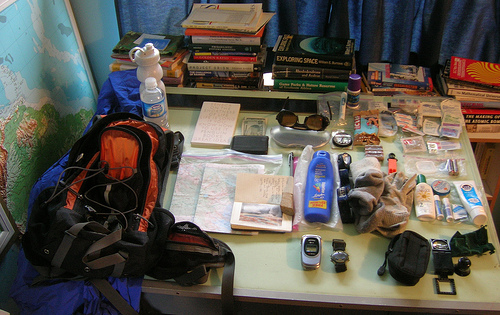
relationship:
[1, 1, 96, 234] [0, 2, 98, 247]
map on wall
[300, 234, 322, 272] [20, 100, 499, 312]
cell phone on desk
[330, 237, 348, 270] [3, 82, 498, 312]
watch on desk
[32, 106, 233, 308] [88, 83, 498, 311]
backpack on desk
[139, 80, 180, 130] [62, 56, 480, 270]
water on desk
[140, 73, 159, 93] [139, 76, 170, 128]
cap on bottle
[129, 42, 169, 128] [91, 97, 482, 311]
bottle on desk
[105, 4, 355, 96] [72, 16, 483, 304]
books near desk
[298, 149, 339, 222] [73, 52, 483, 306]
bottle on desk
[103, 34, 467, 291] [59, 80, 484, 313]
clutter on desk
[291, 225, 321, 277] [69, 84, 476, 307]
cell phone on table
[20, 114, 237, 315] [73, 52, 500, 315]
backpack on desk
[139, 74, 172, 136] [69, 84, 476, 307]
bottle on table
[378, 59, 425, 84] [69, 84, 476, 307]
map on table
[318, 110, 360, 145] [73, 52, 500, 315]
bottle on desk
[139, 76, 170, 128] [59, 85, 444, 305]
bottle on table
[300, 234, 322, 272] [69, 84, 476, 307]
cell phone on table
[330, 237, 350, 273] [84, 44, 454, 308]
watch on table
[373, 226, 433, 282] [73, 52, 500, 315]
bag on desk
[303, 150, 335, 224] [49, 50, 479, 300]
bottle on table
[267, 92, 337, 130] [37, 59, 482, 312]
sunglasses on table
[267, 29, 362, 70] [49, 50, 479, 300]
book on table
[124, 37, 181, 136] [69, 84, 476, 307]
bottle on table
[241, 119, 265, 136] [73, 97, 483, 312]
cash on table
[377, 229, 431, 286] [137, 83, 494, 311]
camera case on table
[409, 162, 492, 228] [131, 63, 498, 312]
supply on table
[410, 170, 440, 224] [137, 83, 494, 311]
supply on table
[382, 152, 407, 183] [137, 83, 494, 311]
supply on table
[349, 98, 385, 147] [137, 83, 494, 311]
supply on table